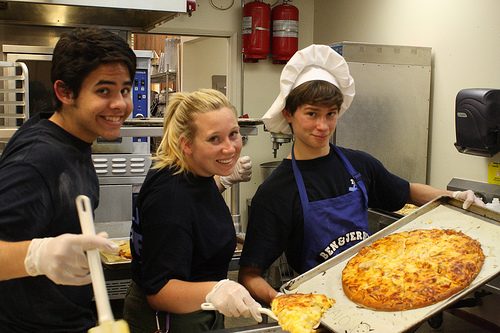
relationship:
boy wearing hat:
[241, 82, 488, 303] [259, 42, 358, 139]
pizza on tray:
[341, 228, 483, 312] [281, 196, 499, 333]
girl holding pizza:
[122, 89, 261, 332] [268, 294, 333, 333]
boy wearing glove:
[2, 25, 137, 333] [25, 232, 119, 287]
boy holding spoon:
[2, 25, 137, 333] [72, 195, 131, 330]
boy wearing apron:
[241, 82, 488, 303] [291, 143, 369, 275]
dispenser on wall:
[455, 88, 499, 158] [149, 2, 499, 233]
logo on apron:
[316, 230, 370, 259] [291, 143, 369, 275]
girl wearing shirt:
[122, 89, 261, 332] [131, 160, 238, 297]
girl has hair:
[122, 89, 261, 332] [149, 88, 241, 183]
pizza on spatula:
[268, 294, 333, 333] [201, 303, 321, 327]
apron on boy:
[291, 143, 369, 275] [241, 82, 488, 303]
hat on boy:
[259, 42, 358, 139] [241, 82, 488, 303]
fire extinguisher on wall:
[242, 0, 270, 61] [149, 2, 499, 233]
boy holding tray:
[241, 82, 488, 303] [281, 196, 499, 333]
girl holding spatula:
[122, 89, 261, 332] [201, 303, 321, 327]